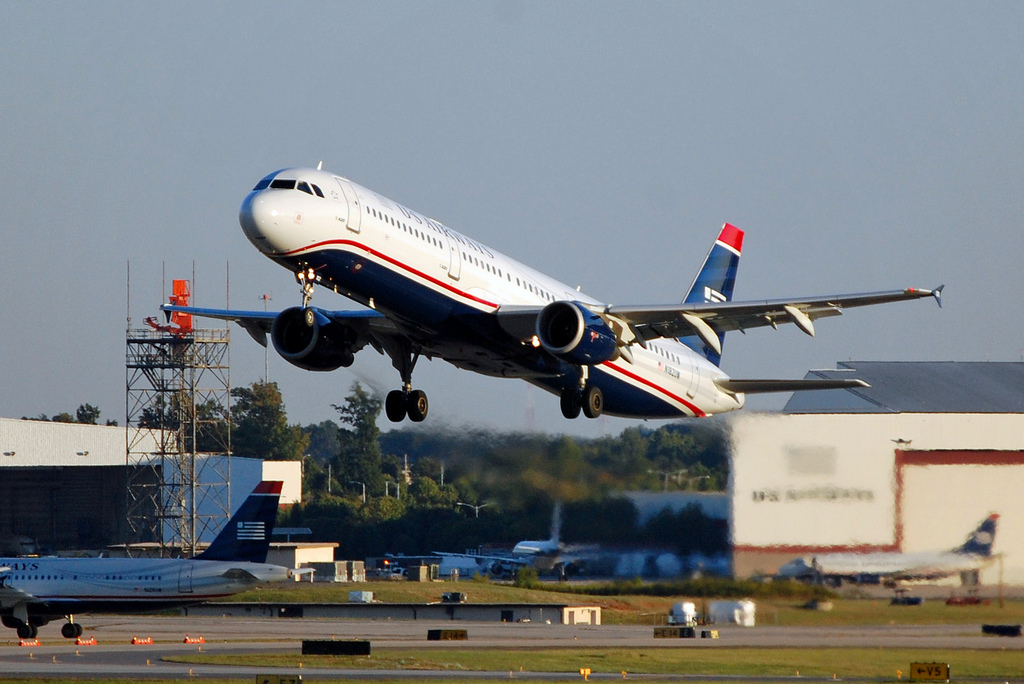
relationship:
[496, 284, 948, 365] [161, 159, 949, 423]
wing attached to airplane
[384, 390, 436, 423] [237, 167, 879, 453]
wheel attached on airplane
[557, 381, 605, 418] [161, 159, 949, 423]
wheels are attached to airplane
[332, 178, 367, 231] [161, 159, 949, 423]
doors are on airplane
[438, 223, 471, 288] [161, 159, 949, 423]
doors are on airplane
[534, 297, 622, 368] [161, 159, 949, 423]
engine attached to airplane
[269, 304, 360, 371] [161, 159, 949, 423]
engine attached to airplane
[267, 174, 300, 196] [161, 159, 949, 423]
window on airplane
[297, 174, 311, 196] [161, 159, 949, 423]
window on airplane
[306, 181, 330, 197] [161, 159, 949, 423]
window on airplane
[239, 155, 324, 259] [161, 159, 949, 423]
nose on airplane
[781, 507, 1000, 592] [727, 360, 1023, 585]
plane next to hangar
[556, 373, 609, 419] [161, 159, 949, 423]
wheel on airplane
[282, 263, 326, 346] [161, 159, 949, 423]
wheel on airplane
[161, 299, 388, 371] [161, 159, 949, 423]
wing on airplane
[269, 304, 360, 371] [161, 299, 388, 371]
engine attached to wing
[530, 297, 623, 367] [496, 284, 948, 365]
engine attached to wing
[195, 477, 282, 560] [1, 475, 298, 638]
tail attached to plane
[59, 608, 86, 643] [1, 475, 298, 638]
wheel attached to plane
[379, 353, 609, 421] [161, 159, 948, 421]
landing gear on airplane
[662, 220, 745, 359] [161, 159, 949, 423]
tail on airplane